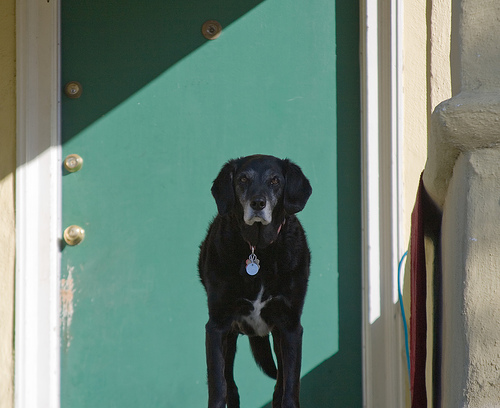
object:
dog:
[198, 152, 314, 406]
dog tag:
[245, 247, 261, 275]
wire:
[395, 245, 414, 407]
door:
[61, 0, 362, 406]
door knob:
[63, 225, 84, 249]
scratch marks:
[60, 263, 76, 353]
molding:
[16, 0, 58, 407]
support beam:
[421, 0, 498, 405]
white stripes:
[226, 286, 277, 339]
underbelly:
[239, 300, 272, 337]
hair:
[221, 153, 300, 183]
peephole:
[202, 20, 221, 37]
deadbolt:
[67, 82, 81, 95]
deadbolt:
[63, 154, 82, 172]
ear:
[280, 158, 312, 214]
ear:
[210, 157, 237, 215]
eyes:
[270, 176, 282, 186]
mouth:
[243, 204, 272, 225]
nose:
[250, 198, 266, 210]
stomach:
[236, 314, 276, 337]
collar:
[235, 216, 283, 247]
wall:
[3, 0, 17, 406]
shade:
[1, 0, 267, 186]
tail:
[250, 333, 278, 380]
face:
[233, 158, 287, 214]